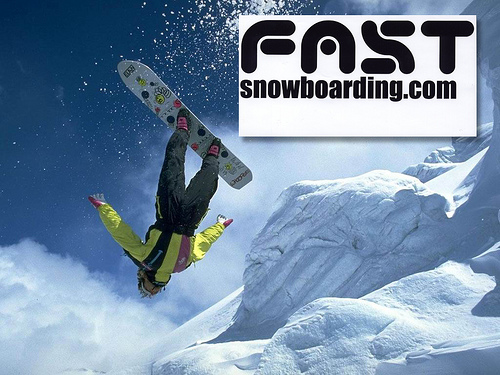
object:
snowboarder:
[86, 108, 234, 300]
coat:
[96, 202, 226, 290]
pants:
[152, 127, 221, 236]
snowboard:
[115, 60, 254, 191]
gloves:
[216, 213, 234, 229]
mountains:
[141, 0, 500, 375]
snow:
[140, 0, 500, 374]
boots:
[206, 137, 222, 159]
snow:
[5, 0, 351, 172]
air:
[0, 0, 493, 375]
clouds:
[0, 233, 179, 375]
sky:
[0, 0, 500, 375]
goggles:
[143, 278, 164, 295]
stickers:
[135, 75, 149, 88]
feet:
[206, 137, 222, 159]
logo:
[240, 18, 475, 102]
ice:
[146, 0, 499, 375]